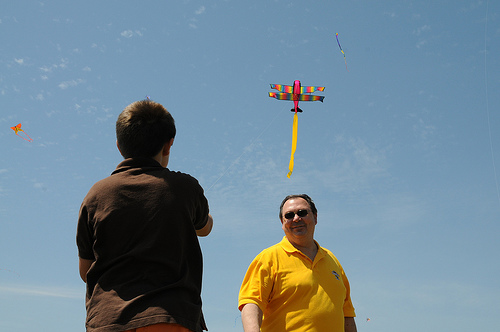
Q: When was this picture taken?
A: Daytime.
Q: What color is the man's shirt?
A: Yellow.